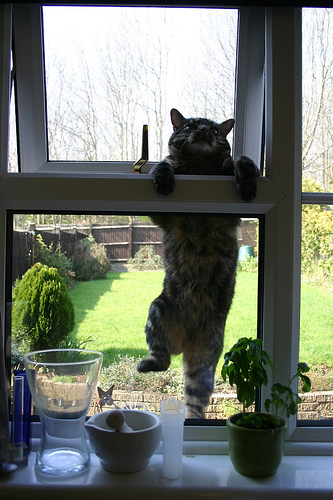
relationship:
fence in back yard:
[12, 221, 256, 276] [33, 262, 331, 391]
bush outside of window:
[12, 258, 81, 358] [17, 6, 257, 421]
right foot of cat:
[130, 352, 164, 375] [135, 105, 267, 419]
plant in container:
[221, 336, 310, 426] [226, 410, 286, 478]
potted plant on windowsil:
[222, 336, 310, 476] [2, 440, 330, 498]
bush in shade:
[12, 258, 78, 358] [42, 275, 103, 340]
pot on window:
[225, 410, 287, 479] [2, 1, 331, 428]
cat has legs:
[135, 105, 267, 419] [121, 151, 269, 210]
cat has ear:
[145, 86, 268, 409] [165, 107, 187, 134]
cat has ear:
[135, 105, 267, 419] [221, 118, 233, 140]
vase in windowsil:
[16, 343, 115, 490] [7, 428, 332, 498]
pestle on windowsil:
[106, 406, 135, 429] [2, 440, 330, 498]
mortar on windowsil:
[88, 407, 166, 475] [2, 440, 330, 498]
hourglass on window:
[31, 349, 92, 477] [17, 6, 257, 421]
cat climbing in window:
[135, 105, 267, 419] [7, 7, 282, 426]